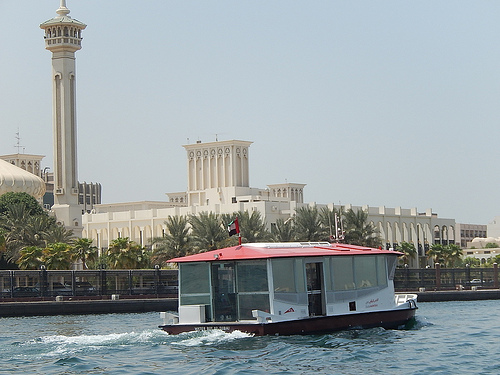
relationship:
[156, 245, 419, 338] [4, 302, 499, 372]
boat on water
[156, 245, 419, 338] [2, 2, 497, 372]
boat in daylight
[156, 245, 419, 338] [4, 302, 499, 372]
boat traveling water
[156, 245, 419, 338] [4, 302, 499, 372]
boat travelling water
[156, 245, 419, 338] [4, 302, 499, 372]
boat near water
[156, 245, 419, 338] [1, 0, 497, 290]
boat near nice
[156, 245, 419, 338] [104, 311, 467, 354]
boat in water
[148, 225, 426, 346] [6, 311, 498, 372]
boat in water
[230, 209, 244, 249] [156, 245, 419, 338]
flag on boat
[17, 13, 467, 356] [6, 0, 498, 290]
photo in afternoon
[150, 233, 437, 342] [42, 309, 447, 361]
houseboat on water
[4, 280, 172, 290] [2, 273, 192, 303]
cars parked in lot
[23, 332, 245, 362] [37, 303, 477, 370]
waves in water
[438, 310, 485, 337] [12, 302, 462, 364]
ripples in water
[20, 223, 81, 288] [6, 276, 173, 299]
tree on land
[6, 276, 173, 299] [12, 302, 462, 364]
land beside water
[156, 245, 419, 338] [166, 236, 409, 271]
boat with a roof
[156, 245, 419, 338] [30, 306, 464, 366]
boat on water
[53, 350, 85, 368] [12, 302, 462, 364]
waves in water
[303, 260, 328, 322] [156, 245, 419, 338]
side door on a boat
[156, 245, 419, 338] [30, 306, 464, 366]
boat in water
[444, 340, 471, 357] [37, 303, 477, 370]
waves in water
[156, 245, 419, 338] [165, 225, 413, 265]
boat with a roof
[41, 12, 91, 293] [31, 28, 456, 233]
tower in background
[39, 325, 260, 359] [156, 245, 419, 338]
wake being left behind boat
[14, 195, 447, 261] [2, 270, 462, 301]
palm trees lining street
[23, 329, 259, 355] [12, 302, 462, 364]
waves in water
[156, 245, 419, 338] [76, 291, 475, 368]
boat in water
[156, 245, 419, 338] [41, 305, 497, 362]
boat in water